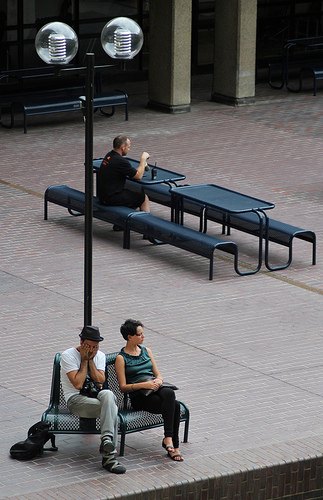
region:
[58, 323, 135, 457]
White shirt on a man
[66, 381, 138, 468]
Jeans on a man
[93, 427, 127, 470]
Shoes on a man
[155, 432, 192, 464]
Sandels on a woman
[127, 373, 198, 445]
Pants on a woman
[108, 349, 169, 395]
Shirt on a woman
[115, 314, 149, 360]
Hair on a woman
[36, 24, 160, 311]
Light post in a square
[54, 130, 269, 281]
Table and benches in a square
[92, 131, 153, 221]
Man sitting at a table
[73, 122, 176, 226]
man sitting at bench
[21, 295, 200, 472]
people sitting on bench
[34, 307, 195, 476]
two people sitting on bench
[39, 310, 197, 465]
couple people sitting on bench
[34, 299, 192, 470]
some people sitting on bench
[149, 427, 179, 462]
feet with open toed shoes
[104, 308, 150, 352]
person with short hair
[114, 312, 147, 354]
person with dark hair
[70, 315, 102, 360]
person wearing a hat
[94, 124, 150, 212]
person wearing dark clothing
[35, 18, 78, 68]
round glass lamp globe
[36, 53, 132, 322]
black metal lamp post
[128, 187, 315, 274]
green metal picnic table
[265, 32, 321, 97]
black metal bicycle rack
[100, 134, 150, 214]
man sitting at picnic table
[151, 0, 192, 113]
grey concrete support column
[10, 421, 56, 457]
black backpack on ground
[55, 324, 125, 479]
man wearing black fedora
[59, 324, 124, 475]
man sitting on bench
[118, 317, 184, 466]
woman wearing flip flops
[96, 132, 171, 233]
man sitting down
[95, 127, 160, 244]
man at a picnic table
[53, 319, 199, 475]
a man and a woman sitting on a bench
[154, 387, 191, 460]
one leg crossed over the other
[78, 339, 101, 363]
both hands on face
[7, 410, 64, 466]
black bag slumped against the bench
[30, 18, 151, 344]
tall, black lamppost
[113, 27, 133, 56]
spiral design on the lightbulb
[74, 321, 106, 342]
black fedora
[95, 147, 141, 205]
black short sleeved shirt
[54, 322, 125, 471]
a man sitting on a bench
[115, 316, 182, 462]
a woman sitting on a bench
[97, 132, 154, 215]
a man sitting on a bench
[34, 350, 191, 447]
a black metal bench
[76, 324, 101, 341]
a black hat on a man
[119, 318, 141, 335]
the black hair of a woman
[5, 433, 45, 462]
the black bag on the ground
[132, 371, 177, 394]
the black bag on the lap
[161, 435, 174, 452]
the foot of the woman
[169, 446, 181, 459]
the foot of the woman